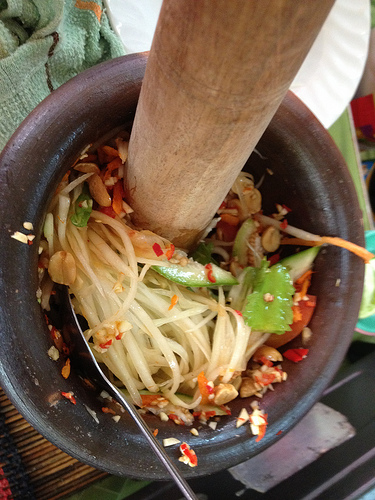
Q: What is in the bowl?
A: Spices.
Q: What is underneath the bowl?
A: Bamboo mat.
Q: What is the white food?
A: Noodles.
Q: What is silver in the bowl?
A: Eating utensil.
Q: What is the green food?
A: Cilantro.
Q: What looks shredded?
A: Food in bowl.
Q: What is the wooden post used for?
A: Grinding.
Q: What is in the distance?
A: White paper plate.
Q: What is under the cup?
A: Bamboo table.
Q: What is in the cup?
A: Mixed food.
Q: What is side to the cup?
A: Green and brown cloth.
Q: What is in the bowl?
A: Wooden stick.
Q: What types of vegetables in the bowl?
A: Tomato.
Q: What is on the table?
A: Towel.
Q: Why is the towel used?
A: To clean.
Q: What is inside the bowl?
A: Sliced vegetables.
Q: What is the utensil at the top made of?
A: Wood.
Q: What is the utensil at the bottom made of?
A: Metal.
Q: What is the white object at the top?
A: Plate.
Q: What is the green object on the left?
A: Towel.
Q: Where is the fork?
A: In the bowl.